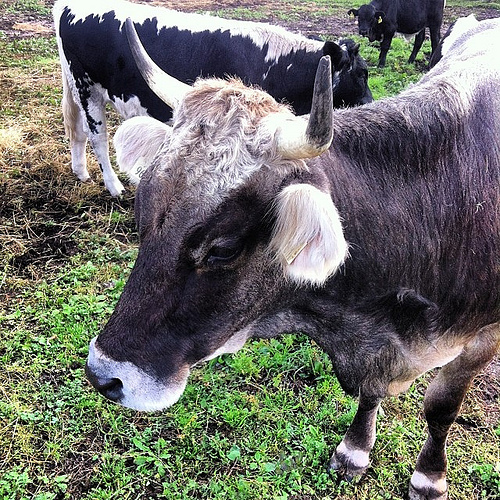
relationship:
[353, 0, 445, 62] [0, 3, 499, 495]
cow standing in field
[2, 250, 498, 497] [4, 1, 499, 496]
weeds growing on field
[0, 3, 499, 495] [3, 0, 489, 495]
field on ground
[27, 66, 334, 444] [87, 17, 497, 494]
head on cow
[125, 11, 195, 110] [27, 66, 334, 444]
horn on head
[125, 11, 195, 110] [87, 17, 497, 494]
horn on cow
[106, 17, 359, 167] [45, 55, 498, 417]
horns on cow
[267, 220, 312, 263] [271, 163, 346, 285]
tag on ear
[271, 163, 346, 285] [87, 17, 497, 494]
ear of cow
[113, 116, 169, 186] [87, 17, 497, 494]
ear of cow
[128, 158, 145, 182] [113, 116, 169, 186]
tag on ear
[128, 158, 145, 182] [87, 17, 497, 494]
tag on cow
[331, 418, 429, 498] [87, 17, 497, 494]
hoofs on cow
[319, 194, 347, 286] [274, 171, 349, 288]
edge of ear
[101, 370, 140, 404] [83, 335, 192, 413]
part of nose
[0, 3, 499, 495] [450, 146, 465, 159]
field on ground